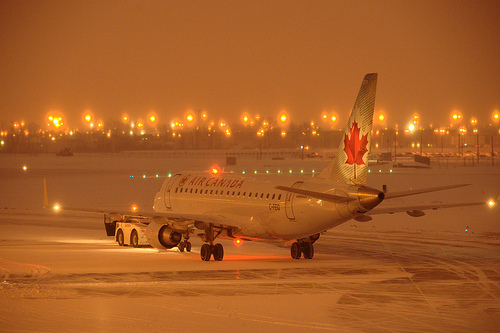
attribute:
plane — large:
[146, 71, 483, 266]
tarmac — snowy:
[0, 229, 498, 331]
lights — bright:
[103, 100, 258, 140]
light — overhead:
[208, 164, 225, 178]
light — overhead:
[428, 102, 489, 135]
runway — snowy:
[13, 160, 482, 310]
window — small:
[172, 186, 283, 201]